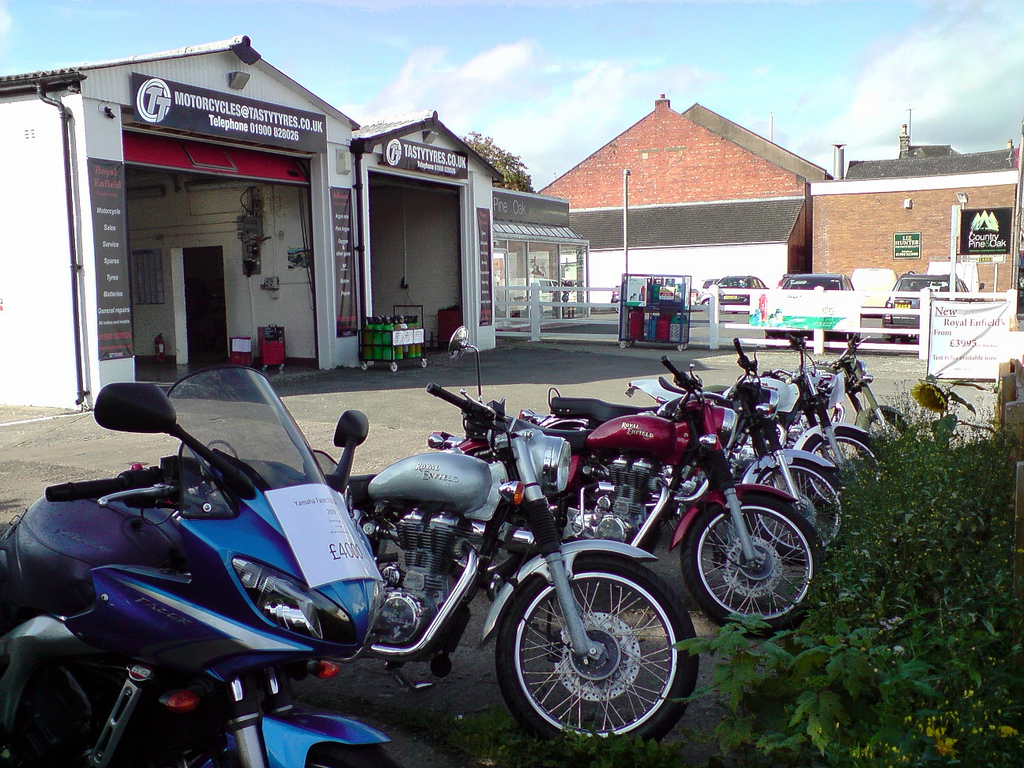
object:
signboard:
[373, 126, 472, 187]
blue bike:
[35, 419, 364, 765]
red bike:
[577, 380, 824, 636]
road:
[0, 365, 1013, 623]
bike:
[749, 324, 920, 462]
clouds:
[393, 33, 1014, 126]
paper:
[264, 477, 388, 589]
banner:
[126, 70, 329, 160]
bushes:
[826, 408, 1023, 762]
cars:
[884, 275, 974, 343]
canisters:
[365, 310, 426, 361]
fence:
[499, 288, 1024, 355]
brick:
[544, 104, 800, 196]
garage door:
[124, 131, 314, 189]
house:
[4, 39, 504, 418]